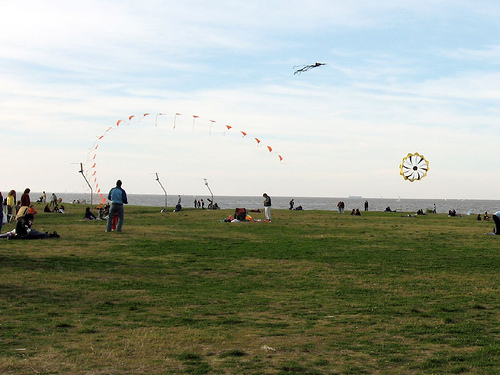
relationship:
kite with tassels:
[279, 50, 332, 88] [157, 100, 289, 174]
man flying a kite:
[105, 180, 126, 234] [289, 61, 325, 77]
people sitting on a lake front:
[0, 204, 59, 240] [0, 202, 499, 374]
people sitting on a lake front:
[85, 203, 109, 223] [0, 202, 499, 374]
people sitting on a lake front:
[226, 206, 251, 224] [0, 202, 499, 374]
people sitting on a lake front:
[350, 208, 360, 216] [0, 202, 499, 374]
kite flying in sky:
[398, 151, 430, 182] [8, 3, 498, 215]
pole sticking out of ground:
[202, 177, 214, 208] [0, 203, 498, 371]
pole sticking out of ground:
[155, 174, 167, 209] [0, 203, 498, 371]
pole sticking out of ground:
[78, 163, 93, 201] [0, 203, 498, 371]